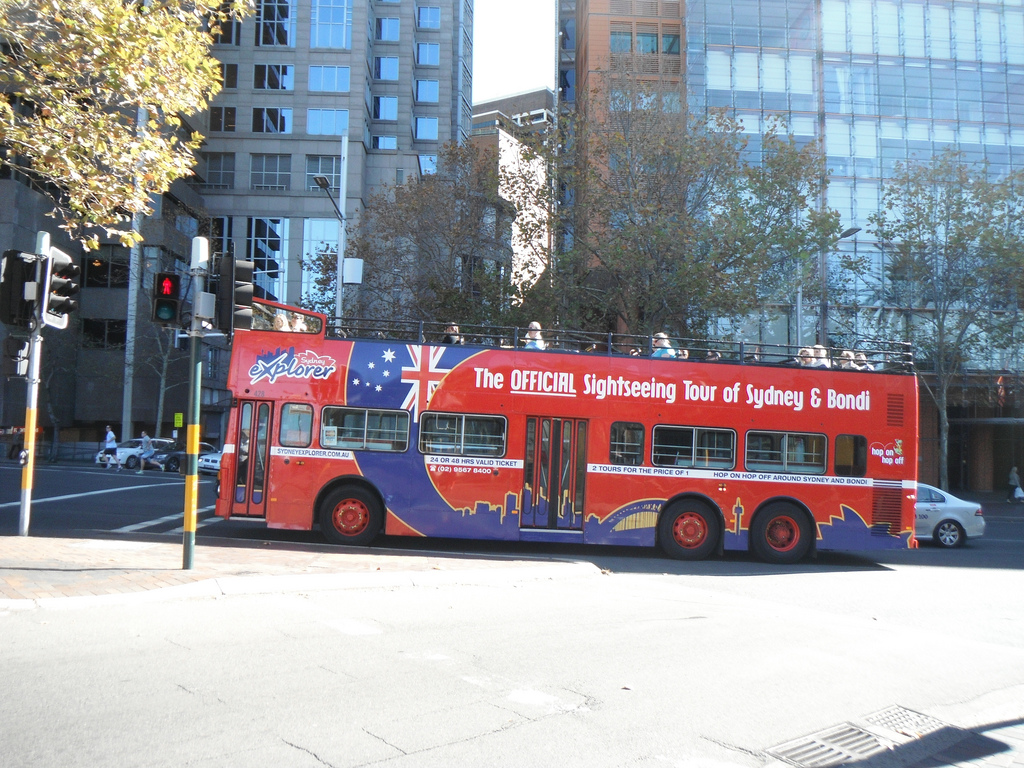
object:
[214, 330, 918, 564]
bus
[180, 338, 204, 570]
post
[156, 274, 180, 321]
traffic light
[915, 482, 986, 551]
car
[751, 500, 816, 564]
wheel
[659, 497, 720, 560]
wheel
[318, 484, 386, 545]
wheel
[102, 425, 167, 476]
people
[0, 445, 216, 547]
street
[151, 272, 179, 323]
crosswalk light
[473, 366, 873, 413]
writing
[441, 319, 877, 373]
people